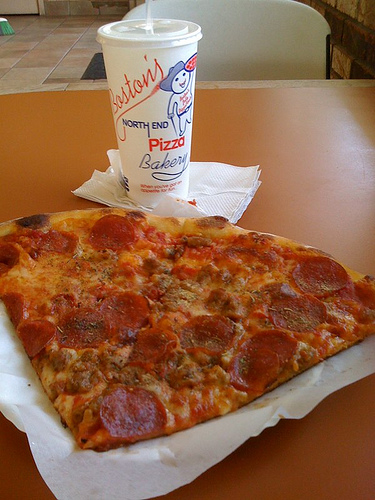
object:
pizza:
[0, 204, 375, 451]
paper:
[0, 284, 375, 500]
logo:
[145, 134, 187, 157]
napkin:
[69, 134, 264, 228]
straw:
[144, 0, 155, 30]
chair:
[120, 0, 343, 78]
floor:
[0, 17, 129, 94]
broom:
[0, 14, 15, 39]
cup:
[93, 9, 202, 202]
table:
[0, 76, 375, 500]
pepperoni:
[237, 329, 290, 377]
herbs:
[53, 342, 67, 362]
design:
[110, 47, 189, 175]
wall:
[295, 0, 374, 81]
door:
[3, 1, 42, 11]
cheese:
[141, 276, 198, 308]